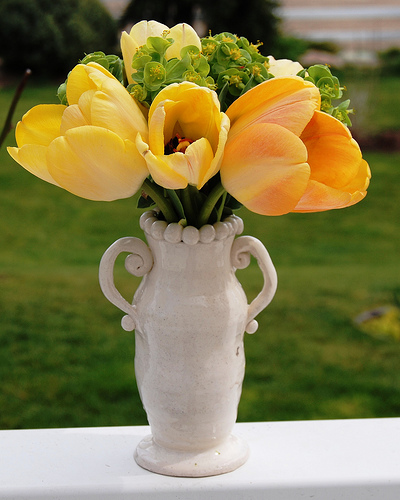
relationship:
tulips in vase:
[52, 47, 377, 220] [92, 216, 279, 477]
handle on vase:
[230, 235, 278, 334] [92, 216, 279, 477]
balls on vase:
[140, 208, 244, 245] [92, 216, 279, 477]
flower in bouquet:
[219, 75, 370, 217] [11, 14, 382, 238]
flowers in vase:
[120, 19, 170, 84] [97, 209, 277, 478]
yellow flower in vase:
[264, 55, 305, 80] [97, 209, 277, 478]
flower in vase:
[219, 75, 370, 217] [97, 209, 277, 478]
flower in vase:
[135, 80, 230, 190] [97, 209, 277, 478]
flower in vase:
[6, 61, 150, 202] [97, 209, 277, 478]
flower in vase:
[140, 80, 233, 195] [92, 216, 279, 477]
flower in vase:
[219, 75, 370, 217] [92, 216, 279, 477]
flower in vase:
[157, 19, 197, 57] [133, 223, 254, 499]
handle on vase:
[96, 235, 149, 327] [92, 216, 279, 477]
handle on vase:
[98, 236, 153, 332] [92, 216, 279, 477]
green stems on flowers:
[141, 187, 229, 221] [5, 15, 374, 218]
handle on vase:
[229, 214, 282, 353] [92, 216, 279, 477]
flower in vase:
[6, 61, 150, 202] [100, 200, 283, 475]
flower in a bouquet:
[6, 61, 150, 202] [4, 18, 372, 478]